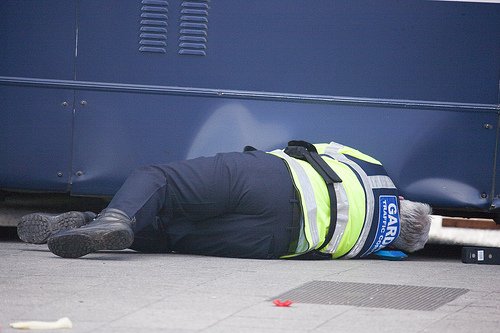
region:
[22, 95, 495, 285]
man checking under train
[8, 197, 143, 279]
man wearing black boots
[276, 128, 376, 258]
man wearing neon vest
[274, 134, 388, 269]
man wearing neon green clothing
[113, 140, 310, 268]
man wearing black slacks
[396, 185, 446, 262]
man with white hair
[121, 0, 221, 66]
navy blue train vent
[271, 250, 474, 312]
vent on cement walkway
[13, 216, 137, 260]
soles of black shoes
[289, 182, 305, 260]
man's black belt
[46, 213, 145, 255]
Black boot on man's foot.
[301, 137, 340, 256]
Black belt around man's waist.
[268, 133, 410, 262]
Security jacket on man.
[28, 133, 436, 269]
Man laying on the ground.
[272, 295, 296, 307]
Red trash on the ground.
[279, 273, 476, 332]
Water drain on the floor.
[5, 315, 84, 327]
Latex glove on the ground.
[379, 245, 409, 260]
Cushion under the man.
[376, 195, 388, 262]
Words traffic control across the back.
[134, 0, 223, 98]
Side of a blue container.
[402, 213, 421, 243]
man hair is short and grey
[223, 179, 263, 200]
man is wearing blue pants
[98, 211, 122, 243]
man has on black boots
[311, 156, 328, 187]
black belt going around waist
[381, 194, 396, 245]
blue sign on the back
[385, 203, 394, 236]
words are in all white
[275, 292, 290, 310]
red wrapper on the floor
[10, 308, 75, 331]
white paper laying on floor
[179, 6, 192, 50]
vents are made on the side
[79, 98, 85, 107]
bolts are on the side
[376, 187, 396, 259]
The blue patch on the back of the man's vest.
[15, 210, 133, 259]
The black boots the guy is wearing.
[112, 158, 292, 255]
The dark blue pants the man is wearing.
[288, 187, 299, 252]
The belt on the man's pants.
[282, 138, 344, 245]
The black belt around the man's vest.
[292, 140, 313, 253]
The gray stripe at the bottom of the man's vest.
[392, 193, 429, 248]
The man's short gray hair.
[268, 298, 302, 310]
The red item on the ground.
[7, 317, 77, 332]
The white item on the ground on the left.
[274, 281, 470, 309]
The grated vent on the sidewalk.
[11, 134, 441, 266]
man lying on the floor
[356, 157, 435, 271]
man has gray hair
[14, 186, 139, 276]
shoes of man are black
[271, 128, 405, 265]
man wears a vest color green and gray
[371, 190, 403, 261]
white letters on blue background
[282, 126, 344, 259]
a belt on wrist of man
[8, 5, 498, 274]
man looking below a bus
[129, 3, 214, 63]
vents on a bus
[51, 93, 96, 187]
screws on a bus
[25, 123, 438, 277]
man wears black pants